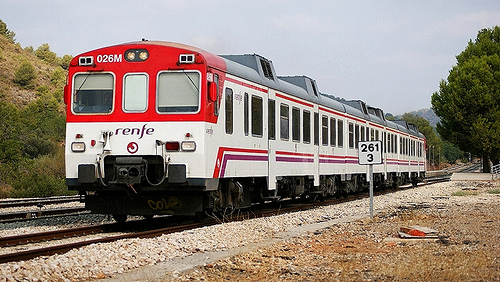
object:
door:
[268, 89, 275, 190]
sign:
[357, 140, 382, 165]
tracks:
[1, 193, 452, 262]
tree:
[432, 28, 497, 173]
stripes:
[212, 146, 427, 177]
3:
[364, 153, 376, 164]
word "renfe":
[110, 121, 157, 140]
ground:
[171, 180, 499, 282]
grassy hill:
[0, 20, 68, 198]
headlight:
[182, 141, 196, 151]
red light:
[164, 140, 181, 152]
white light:
[179, 138, 197, 153]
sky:
[3, 0, 498, 111]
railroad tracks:
[26, 215, 197, 256]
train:
[63, 37, 427, 223]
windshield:
[72, 71, 113, 115]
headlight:
[70, 141, 87, 153]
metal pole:
[368, 165, 374, 219]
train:
[64, 22, 426, 222]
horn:
[96, 130, 114, 152]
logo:
[111, 122, 162, 139]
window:
[157, 68, 203, 114]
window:
[73, 71, 198, 115]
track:
[0, 215, 205, 261]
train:
[67, 41, 433, 182]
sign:
[357, 140, 382, 218]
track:
[0, 180, 498, 279]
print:
[95, 54, 121, 62]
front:
[65, 39, 207, 215]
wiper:
[73, 68, 92, 98]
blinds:
[156, 70, 200, 114]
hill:
[0, 20, 66, 197]